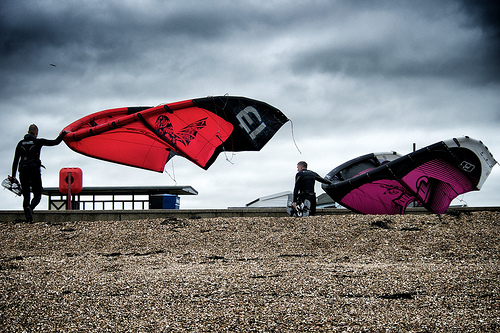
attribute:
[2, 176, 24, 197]
packet — gray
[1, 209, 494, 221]
pavement — tan, black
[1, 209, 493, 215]
tan — rough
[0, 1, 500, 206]
skies — overcast, gray, white, blue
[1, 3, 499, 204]
clouds — stormy, dark, gray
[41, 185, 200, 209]
bench — long, gray, white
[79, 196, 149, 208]
partition — steel made, metallic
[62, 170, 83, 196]
container — on bench, orange, red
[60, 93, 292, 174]
fabric — red, black, large, flying, white, big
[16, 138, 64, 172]
shirt — black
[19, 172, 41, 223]
pants — black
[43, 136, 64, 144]
sleeve — long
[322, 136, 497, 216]
object — large, pink, black, purple, gray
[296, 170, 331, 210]
outfit — black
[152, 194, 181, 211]
box — black, blue, white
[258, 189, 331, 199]
roof — white, brown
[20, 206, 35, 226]
shoes — black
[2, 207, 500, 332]
on ground — rocky, sandy, gravel, light brown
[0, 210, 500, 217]
platform — long, wooded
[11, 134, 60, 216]
uniform — black, wet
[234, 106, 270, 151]
design — black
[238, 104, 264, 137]
letters — e&i, white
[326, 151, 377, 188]
trim — black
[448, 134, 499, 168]
tips — white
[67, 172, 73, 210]
post — red